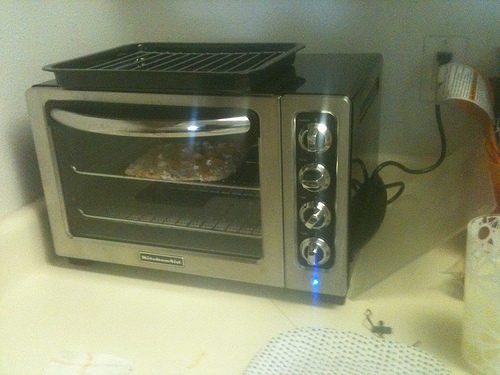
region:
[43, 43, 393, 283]
silver convection oven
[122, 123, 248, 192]
pizza cooking on silver rack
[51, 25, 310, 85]
black tray with black rack on top of oven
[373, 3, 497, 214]
black cord plugged into wall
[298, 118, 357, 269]
four silver knobs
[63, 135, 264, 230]
two racks in the oven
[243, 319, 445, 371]
white pot holder with blue dots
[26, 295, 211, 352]
solid white counter top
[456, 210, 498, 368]
glass with liquid in it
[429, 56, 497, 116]
white tag attached to black cord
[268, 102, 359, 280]
Knobs on the oven.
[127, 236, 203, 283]
Logo on the oven.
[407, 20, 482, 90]
Plug in the wall.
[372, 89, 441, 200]
Cord on the wall.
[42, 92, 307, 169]
Handle on the oven.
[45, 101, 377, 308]
Door on the oven.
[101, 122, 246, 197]
Food in the oven.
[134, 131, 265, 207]
pizza in the oven.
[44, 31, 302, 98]
Pan on the oven.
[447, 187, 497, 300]
Glass on the table.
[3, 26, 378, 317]
a square toaster oven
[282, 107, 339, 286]
four knobs on the oven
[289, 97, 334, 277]
the knobs are silver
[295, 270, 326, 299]
a blue light on the front bottom of the oven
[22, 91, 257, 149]
a silver handle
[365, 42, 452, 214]
a chord plugged in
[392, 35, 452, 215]
the chord is black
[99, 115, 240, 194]
a pizza in the oven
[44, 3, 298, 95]
a tray on top of the oven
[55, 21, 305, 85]
the tray is black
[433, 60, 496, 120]
informational card on an appliance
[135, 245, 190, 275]
manufacturer's name plate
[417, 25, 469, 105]
electrical outlet in use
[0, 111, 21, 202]
section of white wall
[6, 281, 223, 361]
white counter top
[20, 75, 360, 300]
a toaster oven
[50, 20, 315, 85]
pan and grill on top of the oven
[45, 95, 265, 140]
oven's door handle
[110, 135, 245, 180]
food inside the appliance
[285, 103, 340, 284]
four control dials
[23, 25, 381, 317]
toaster oven on a counter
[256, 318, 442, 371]
pot holder on a counter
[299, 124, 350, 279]
knobs on a toaster oven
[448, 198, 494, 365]
glass on a counter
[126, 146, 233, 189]
food cooking in oven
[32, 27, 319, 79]
black tray on toaster oven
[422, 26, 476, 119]
outlet cover in a kitchen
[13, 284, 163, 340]
beige counter in a kitchen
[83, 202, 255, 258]
rack in a toaster oven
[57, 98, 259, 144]
metal handle of a toaster oven